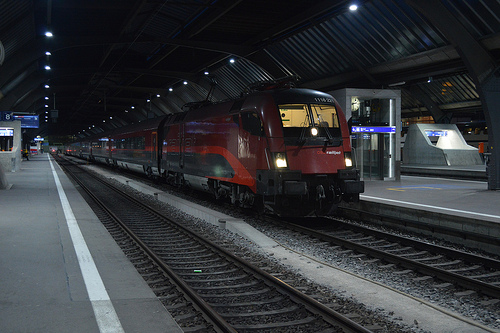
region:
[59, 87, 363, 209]
a long red train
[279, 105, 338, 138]
a lit conductors cabin of a train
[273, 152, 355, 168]
headlights of a red train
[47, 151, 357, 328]
long black train tracks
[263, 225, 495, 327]
gravel between the train tracks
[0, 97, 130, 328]
a long train station walkway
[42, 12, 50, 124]
a long row of lights on the roof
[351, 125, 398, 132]
a thin purple sign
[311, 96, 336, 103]
white numbers on a red train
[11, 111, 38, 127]
a sign hanging from the roof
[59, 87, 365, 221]
a red and black train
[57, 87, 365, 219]
a black and red train in a train station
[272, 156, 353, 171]
headlights on the front of the red and black train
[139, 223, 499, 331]
two railroad tracks inside the train station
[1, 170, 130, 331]
pedestrian walkway beside the train tracks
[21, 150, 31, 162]
a man sitting a chair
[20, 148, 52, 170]
a man sitting in a chair on the pedestrian walkway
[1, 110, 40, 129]
a blue sign on a medal pole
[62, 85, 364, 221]
a red and black train picking up passengers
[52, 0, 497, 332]
a train inside a train station to pickup passengers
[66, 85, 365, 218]
A long red, orange and black train.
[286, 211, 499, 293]
A brown train track in front of a train.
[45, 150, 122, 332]
A white line all the way down the grey walkway to the left of a train.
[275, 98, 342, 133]
Two front windows of a red train.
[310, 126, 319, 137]
Front round light of a train.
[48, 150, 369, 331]
Long brown train track with no train visible.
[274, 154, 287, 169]
A red trains left headlight that is illuminated.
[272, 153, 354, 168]
Two illuminated square headlights on the bottom of a train.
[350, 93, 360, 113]
Half of a white and black clock to the right of a train.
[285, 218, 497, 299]
Brown tracks in front of a red train.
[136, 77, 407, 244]
a train on train tracks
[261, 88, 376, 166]
the windshield on a train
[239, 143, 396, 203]
the headlights on atrain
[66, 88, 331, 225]
a really long train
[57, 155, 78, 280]
a white line near train tracks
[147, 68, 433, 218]
a train passing through a station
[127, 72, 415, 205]
a train rolling on train tracks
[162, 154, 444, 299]
two train tracks side by side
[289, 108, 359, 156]
windshield wipers on a train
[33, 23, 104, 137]
a lot of lights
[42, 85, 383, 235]
Train on the tracks.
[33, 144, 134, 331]
White line besides the tracks.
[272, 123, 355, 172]
Head lights on the train.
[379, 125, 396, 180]
Steel pole in the background.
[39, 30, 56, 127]
Lights in the ceiling.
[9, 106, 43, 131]
blue sign in the background.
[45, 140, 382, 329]
metal train tracks beside train.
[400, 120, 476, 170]
Concrete lighted structure in the background.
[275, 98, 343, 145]
Front windows on the train.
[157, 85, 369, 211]
Maroon, red, and black on the train.